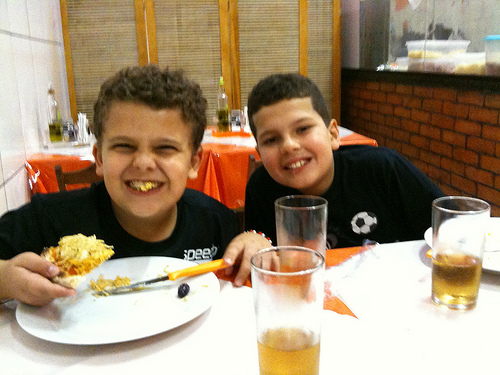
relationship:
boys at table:
[1, 64, 454, 308] [0, 237, 500, 374]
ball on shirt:
[351, 210, 379, 236] [243, 146, 459, 247]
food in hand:
[41, 234, 116, 279] [6, 251, 76, 309]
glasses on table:
[249, 196, 499, 373] [0, 237, 500, 374]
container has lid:
[483, 33, 499, 77] [485, 35, 498, 42]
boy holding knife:
[244, 73, 462, 249] [89, 257, 232, 294]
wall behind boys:
[343, 74, 500, 217] [1, 64, 454, 308]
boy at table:
[244, 73, 462, 249] [0, 237, 500, 374]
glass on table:
[251, 247, 323, 373] [0, 237, 500, 374]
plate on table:
[14, 254, 221, 346] [0, 237, 500, 374]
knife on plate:
[89, 257, 232, 294] [14, 254, 221, 346]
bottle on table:
[217, 76, 230, 137] [27, 122, 379, 210]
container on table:
[483, 33, 499, 77] [343, 62, 497, 101]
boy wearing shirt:
[244, 73, 462, 249] [243, 146, 459, 247]